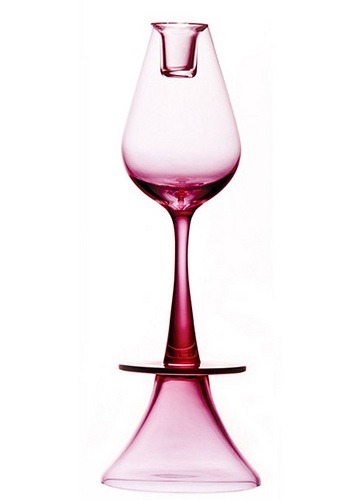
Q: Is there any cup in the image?
A: Yes, there is a cup.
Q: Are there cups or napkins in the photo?
A: Yes, there is a cup.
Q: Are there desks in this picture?
A: No, there are no desks.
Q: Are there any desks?
A: No, there are no desks.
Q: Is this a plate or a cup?
A: This is a cup.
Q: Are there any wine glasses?
A: Yes, there is a wine glass.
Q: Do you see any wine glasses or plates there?
A: Yes, there is a wine glass.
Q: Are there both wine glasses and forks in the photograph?
A: No, there is a wine glass but no forks.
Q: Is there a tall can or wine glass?
A: Yes, there is a tall wine glass.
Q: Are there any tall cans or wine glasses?
A: Yes, there is a tall wine glass.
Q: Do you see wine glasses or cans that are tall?
A: Yes, the wine glass is tall.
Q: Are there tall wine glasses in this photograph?
A: Yes, there is a tall wine glass.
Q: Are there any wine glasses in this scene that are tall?
A: Yes, there is a wine glass that is tall.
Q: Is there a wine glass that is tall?
A: Yes, there is a wine glass that is tall.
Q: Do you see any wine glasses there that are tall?
A: Yes, there is a wine glass that is tall.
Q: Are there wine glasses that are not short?
A: Yes, there is a tall wine glass.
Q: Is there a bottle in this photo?
A: No, there are no bottles.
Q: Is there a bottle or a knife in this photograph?
A: No, there are no bottles or knives.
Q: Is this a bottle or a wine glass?
A: This is a wine glass.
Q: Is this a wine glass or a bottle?
A: This is a wine glass.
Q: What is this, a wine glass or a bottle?
A: This is a wine glass.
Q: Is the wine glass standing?
A: Yes, the wine glass is standing.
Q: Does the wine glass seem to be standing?
A: Yes, the wine glass is standing.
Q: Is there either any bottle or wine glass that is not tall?
A: No, there is a wine glass but it is tall.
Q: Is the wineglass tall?
A: Yes, the wineglass is tall.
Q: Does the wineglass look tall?
A: Yes, the wineglass is tall.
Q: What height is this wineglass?
A: The wineglass is tall.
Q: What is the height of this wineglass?
A: The wineglass is tall.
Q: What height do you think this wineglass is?
A: The wineglass is tall.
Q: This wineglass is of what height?
A: The wineglass is tall.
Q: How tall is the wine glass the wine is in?
A: The wineglass is tall.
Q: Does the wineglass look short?
A: No, the wineglass is tall.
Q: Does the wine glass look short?
A: No, the wine glass is tall.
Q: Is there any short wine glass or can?
A: No, there is a wine glass but it is tall.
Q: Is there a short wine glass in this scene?
A: No, there is a wine glass but it is tall.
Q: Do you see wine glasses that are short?
A: No, there is a wine glass but it is tall.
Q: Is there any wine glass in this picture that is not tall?
A: No, there is a wine glass but it is tall.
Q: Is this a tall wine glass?
A: Yes, this is a tall wine glass.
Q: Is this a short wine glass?
A: No, this is a tall wine glass.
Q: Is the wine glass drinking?
A: Yes, the wine glass is drinking.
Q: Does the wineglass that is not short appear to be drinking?
A: Yes, the wine glass is drinking.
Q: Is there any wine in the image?
A: Yes, there is wine.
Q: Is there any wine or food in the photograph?
A: Yes, there is wine.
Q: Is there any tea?
A: No, there is no tea.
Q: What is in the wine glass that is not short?
A: The wine is in the wineglass.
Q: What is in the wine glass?
A: The wine is in the wineglass.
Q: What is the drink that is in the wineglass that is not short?
A: The drink is wine.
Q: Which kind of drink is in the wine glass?
A: The drink is wine.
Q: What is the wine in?
A: The wine is in the wineglass.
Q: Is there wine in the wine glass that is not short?
A: Yes, there is wine in the wineglass.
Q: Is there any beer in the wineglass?
A: No, there is wine in the wineglass.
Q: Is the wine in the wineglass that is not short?
A: Yes, the wine is in the wineglass.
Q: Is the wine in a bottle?
A: No, the wine is in the wineglass.